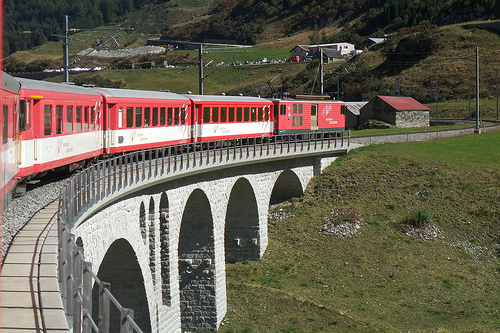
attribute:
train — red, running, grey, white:
[1, 65, 348, 154]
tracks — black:
[1, 111, 477, 267]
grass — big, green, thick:
[25, 36, 497, 332]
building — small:
[359, 93, 433, 131]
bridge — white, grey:
[68, 146, 351, 332]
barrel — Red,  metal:
[295, 52, 302, 62]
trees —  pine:
[3, 0, 152, 53]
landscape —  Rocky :
[272, 199, 498, 259]